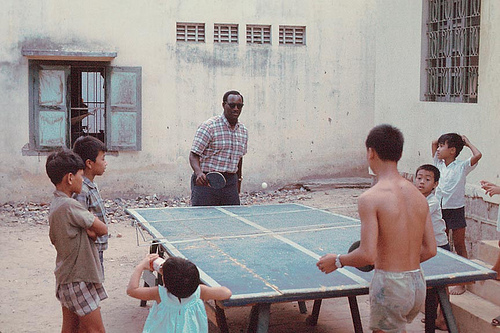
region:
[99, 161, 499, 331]
this is a table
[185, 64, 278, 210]
this is a man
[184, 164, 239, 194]
this is a paddle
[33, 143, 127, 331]
this is a boy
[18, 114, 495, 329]
these are little children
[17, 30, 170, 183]
this is a window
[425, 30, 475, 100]
this is a grating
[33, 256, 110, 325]
these are the shorts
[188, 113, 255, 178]
this is a shirt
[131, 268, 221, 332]
this is a dress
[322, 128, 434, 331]
The boy without a shirt on.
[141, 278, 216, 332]
The child in the blue dress.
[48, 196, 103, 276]
The brown shirt the boy is wearing.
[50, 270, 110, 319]
The plaid shorts the boy in the brown shirt is wearing.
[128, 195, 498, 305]
The ping pong table.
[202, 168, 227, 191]
The ping pong paddle in the man's hand.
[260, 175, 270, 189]
The ping pong ball bouncing in the air.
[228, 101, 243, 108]
The sunglasses the man is wearing.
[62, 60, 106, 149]
The open window on the building.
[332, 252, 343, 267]
The silver watch on the shirtless boy's wrist.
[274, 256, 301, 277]
green paint on table.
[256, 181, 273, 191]
ball in mid air.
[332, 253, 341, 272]
watch on boy's wrist.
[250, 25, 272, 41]
vent on the wall.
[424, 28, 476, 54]
bars over the window.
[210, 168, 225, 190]
paddle in man's hand.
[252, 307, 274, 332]
leg of the table.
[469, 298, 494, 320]
step near the table.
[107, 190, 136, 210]
rubble near the window.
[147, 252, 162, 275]
container in child's hand.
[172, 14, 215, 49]
White vent on building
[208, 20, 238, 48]
White vent on building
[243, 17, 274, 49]
White vent on building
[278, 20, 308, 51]
White vent on building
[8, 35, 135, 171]
Window of a building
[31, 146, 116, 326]
small child standing outside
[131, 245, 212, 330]
small child standing outside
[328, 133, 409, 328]
small child standing outside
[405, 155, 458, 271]
small child standing outside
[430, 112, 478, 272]
small child standing outside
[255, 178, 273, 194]
Ping pong ball in flight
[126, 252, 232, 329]
Child drinking from cup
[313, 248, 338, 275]
Hand of ping pong player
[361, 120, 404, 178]
Head of ping pong player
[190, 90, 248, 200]
Man playing ping pong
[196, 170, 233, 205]
Ping pong game paddle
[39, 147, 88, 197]
Head of child watching game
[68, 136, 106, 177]
Head of child watching game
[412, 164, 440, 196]
Head pf child watching game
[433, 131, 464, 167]
Head of child watching game